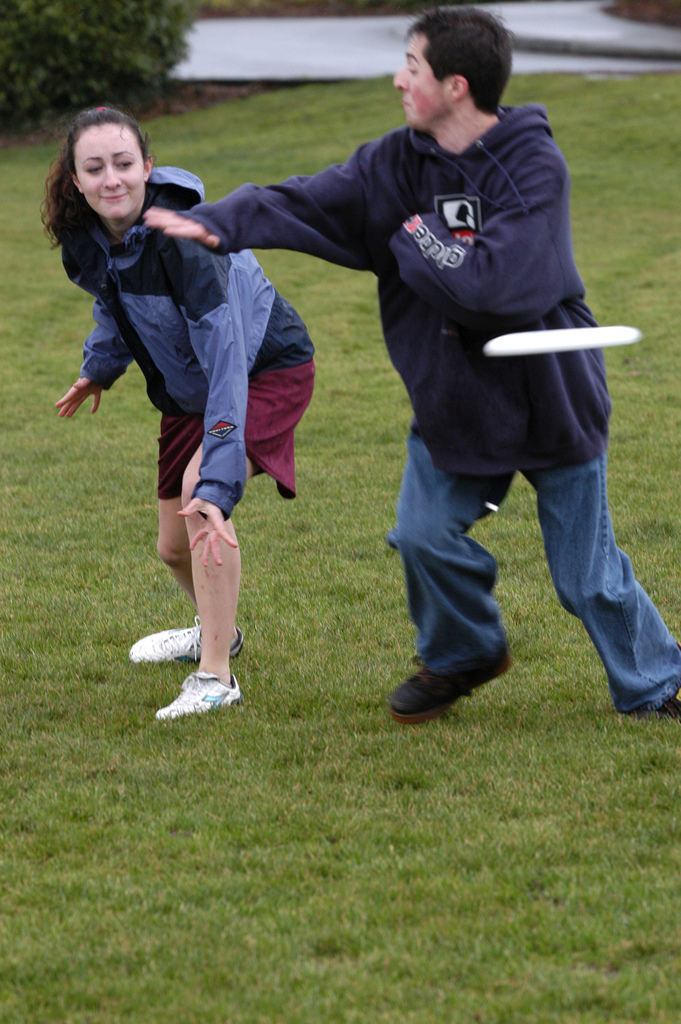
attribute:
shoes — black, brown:
[389, 638, 677, 733]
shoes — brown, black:
[394, 623, 678, 731]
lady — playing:
[77, 245, 292, 675]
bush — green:
[20, 5, 193, 112]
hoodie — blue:
[240, 58, 612, 428]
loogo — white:
[438, 191, 503, 255]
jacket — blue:
[0, 161, 357, 401]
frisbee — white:
[484, 282, 653, 384]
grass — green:
[99, 418, 500, 811]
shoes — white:
[138, 597, 306, 727]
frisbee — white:
[434, 296, 653, 396]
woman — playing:
[79, 171, 365, 632]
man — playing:
[272, 218, 627, 569]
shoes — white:
[111, 594, 346, 800]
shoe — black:
[384, 638, 578, 708]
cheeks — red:
[406, 48, 484, 132]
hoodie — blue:
[360, 233, 637, 458]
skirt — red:
[130, 356, 351, 510]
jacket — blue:
[75, 156, 321, 428]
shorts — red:
[150, 349, 320, 514]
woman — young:
[29, 89, 344, 732]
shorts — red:
[145, 346, 327, 525]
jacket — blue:
[52, 160, 334, 527]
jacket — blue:
[67, 222, 313, 522]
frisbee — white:
[481, 323, 641, 357]